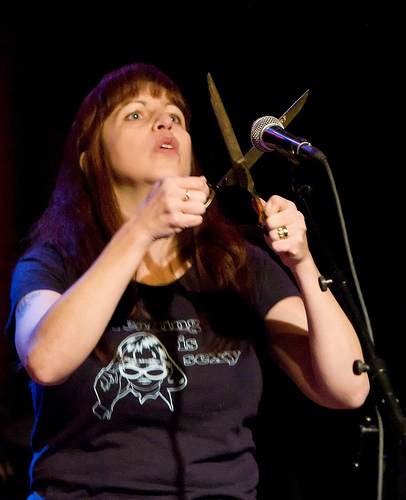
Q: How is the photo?
A: Clear.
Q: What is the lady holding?
A: Scissors.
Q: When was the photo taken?
A: Nighttime.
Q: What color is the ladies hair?
A: Brown.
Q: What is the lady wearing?
A: Clothes.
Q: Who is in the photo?
A: A lady.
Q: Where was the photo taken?
A: On a stage.